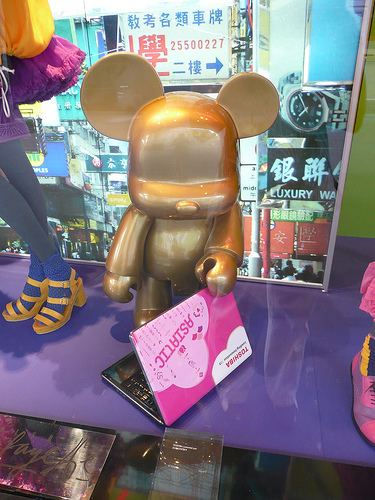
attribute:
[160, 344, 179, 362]
letter — written, pink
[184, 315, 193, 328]
letter — pink, written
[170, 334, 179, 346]
letter — written, pink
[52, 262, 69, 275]
pattern — pink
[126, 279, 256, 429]
letter — written, pink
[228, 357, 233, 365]
letter — written, pink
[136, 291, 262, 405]
letter — written, pink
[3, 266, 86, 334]
shoes — yellow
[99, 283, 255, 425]
laptop — pink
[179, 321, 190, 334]
letter — written, pink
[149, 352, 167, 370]
letter — pink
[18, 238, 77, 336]
socks — blue